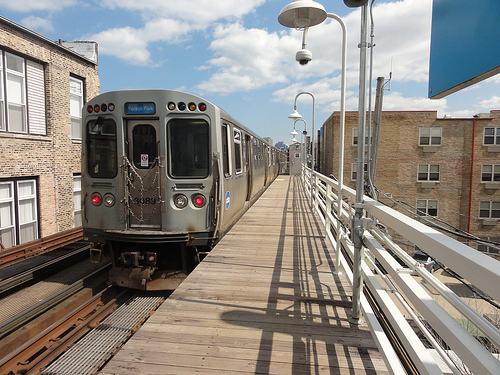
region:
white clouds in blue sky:
[117, 8, 169, 35]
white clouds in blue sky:
[217, 54, 259, 89]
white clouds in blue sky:
[141, 2, 183, 69]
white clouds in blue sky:
[224, 51, 281, 102]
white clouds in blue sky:
[117, 12, 178, 54]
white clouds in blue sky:
[241, 64, 268, 111]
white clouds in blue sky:
[109, 0, 154, 61]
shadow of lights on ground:
[222, 174, 358, 373]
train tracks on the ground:
[1, 288, 122, 367]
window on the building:
[17, 176, 45, 239]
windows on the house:
[418, 124, 446, 150]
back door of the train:
[124, 118, 160, 228]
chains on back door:
[130, 164, 152, 224]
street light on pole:
[289, 104, 307, 125]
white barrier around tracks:
[361, 206, 498, 372]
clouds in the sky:
[219, 29, 270, 86]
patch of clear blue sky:
[107, 70, 144, 86]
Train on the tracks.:
[77, 86, 290, 301]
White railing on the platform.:
[298, 160, 498, 374]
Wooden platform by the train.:
[90, 173, 387, 374]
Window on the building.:
[412, 160, 444, 190]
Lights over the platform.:
[273, 0, 328, 70]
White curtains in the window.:
[2, 178, 40, 251]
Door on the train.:
[121, 113, 163, 230]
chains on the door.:
[119, 150, 165, 229]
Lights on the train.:
[87, 188, 207, 213]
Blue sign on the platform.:
[426, 2, 498, 103]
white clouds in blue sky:
[93, 24, 167, 62]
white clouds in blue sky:
[204, 32, 245, 96]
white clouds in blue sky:
[237, 68, 259, 90]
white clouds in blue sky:
[106, 5, 168, 50]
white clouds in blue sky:
[381, 24, 416, 61]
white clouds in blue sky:
[139, 22, 203, 56]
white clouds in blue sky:
[121, 8, 158, 36]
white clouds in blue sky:
[197, 28, 254, 86]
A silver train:
[74, 64, 310, 271]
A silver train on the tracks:
[58, 74, 297, 272]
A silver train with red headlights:
[82, 87, 217, 257]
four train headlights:
[74, 182, 207, 217]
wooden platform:
[98, 258, 328, 348]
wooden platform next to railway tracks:
[64, 272, 361, 347]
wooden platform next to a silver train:
[106, 64, 325, 297]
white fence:
[401, 217, 451, 369]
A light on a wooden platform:
[265, 1, 353, 287]